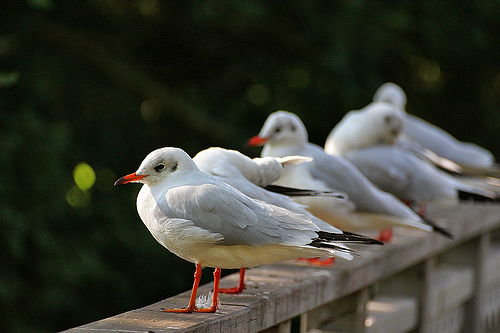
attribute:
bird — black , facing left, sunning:
[113, 144, 385, 314]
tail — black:
[455, 184, 490, 209]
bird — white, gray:
[370, 79, 487, 176]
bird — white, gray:
[317, 97, 498, 215]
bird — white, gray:
[247, 100, 428, 239]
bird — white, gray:
[194, 129, 338, 224]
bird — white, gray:
[117, 141, 327, 319]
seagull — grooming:
[327, 102, 498, 207]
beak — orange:
[113, 173, 140, 185]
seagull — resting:
[126, 96, 408, 277]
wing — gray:
[315, 147, 451, 237]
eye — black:
[153, 159, 166, 173]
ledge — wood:
[85, 167, 498, 327]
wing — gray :
[211, 197, 276, 240]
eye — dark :
[152, 158, 166, 184]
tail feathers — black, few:
[311, 229, 383, 254]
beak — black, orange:
[103, 169, 151, 208]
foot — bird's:
[195, 303, 220, 315]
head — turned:
[365, 96, 404, 147]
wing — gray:
[151, 182, 318, 251]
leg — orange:
[158, 259, 204, 314]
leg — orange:
[191, 257, 221, 313]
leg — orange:
[295, 251, 320, 261]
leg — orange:
[309, 250, 338, 265]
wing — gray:
[307, 150, 408, 220]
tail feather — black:
[419, 213, 456, 241]